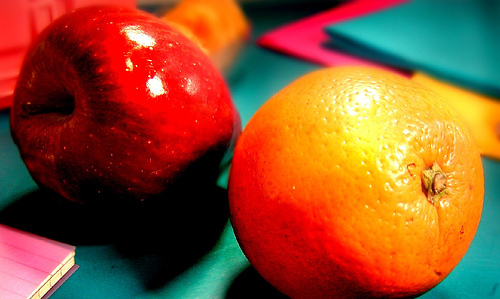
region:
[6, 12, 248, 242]
this is an apple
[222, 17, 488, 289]
this is an orange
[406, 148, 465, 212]
stem on the orange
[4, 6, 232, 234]
the apple is red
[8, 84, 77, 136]
stem on the apple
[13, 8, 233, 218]
A red shiny apple with spots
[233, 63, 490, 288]
A shiny orange with peel and no blemish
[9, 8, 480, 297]
An apple and an orange together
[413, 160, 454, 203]
The broken stem of an orange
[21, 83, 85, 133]
The short stem of a red apple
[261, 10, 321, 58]
Corner of a pink folder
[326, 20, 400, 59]
Corner of a blue folder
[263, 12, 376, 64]
Blue and pink folders sitting on each other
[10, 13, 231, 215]
The red apple on the table.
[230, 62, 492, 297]
The orange on the table.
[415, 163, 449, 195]
The green stem of the orange.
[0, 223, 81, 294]
The notebook next to the apple.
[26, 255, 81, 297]
The paper of the notebook.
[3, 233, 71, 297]
The lines on the paper of the notebook.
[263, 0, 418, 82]
The red folder on the table.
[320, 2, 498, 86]
The bluish green colored folder on the table.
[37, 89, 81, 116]
The indention in the center of the apple.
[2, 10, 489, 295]
The table the fruits are on.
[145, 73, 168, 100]
light reflection on apple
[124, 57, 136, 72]
light reflection on apple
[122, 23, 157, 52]
light reflection on apple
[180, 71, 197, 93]
light reflection on apple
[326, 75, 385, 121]
light reflection on orange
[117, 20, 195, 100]
light reflections on apple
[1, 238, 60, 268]
line on notebook paper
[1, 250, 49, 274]
line on notebook paper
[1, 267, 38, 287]
line on notebook paper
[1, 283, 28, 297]
line on notebook paper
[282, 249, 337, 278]
motorcycle in a field with gravel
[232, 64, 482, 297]
unpeeled orange orange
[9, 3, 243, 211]
shiny red whole apple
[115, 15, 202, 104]
light reflected on an apple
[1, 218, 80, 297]
notebook with pink plastic cover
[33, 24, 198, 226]
A fruit on a table.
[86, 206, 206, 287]
A blue part of a table.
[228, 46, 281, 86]
A blue part of a table.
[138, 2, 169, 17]
A blue part of a table.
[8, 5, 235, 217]
The apple is red.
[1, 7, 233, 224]
The apple is shiny.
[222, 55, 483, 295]
The orange is next to the apple.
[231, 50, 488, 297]
The orange is shiny.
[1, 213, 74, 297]
The notebook has a pink cover.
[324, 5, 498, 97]
The top folder is blue.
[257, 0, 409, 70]
The bottom folder is pink.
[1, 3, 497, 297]
The desk is blue.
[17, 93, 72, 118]
The stem of the apple is brown.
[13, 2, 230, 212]
The apple is next to the orange.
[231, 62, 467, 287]
Orange next to a apple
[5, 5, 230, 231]
apple next to a orange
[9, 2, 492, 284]
apple and orange on a table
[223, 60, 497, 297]
Orange on a table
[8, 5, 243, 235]
apple on a table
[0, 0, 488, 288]
apple and orange on a table